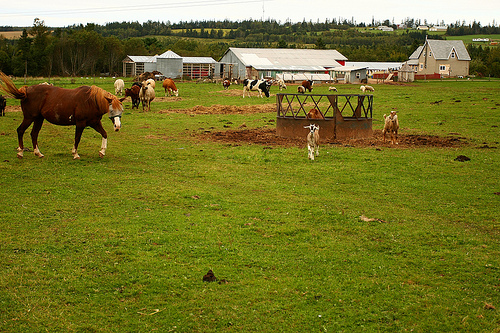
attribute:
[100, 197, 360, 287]
field — green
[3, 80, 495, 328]
field — green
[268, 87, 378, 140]
pen — brown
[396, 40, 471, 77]
house — tan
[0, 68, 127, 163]
horse — brown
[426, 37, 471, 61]
roof — grey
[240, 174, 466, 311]
grass — green, short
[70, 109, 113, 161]
legs — brown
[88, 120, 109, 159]
leg — brown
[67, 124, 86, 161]
leg — brown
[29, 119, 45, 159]
leg — brown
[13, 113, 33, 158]
leg — brown